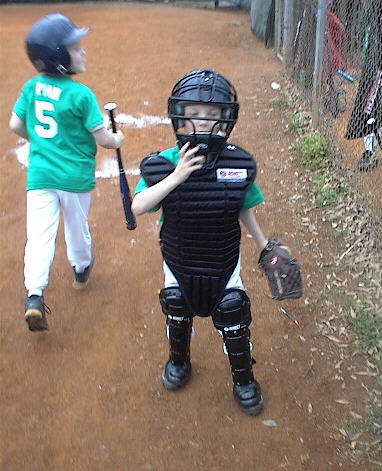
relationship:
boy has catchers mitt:
[130, 67, 291, 416] [257, 236, 303, 302]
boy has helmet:
[10, 12, 126, 331] [15, 10, 100, 70]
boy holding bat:
[10, 12, 126, 331] [102, 101, 136, 229]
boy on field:
[10, 12, 126, 331] [7, 0, 362, 457]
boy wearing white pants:
[5, 10, 137, 329] [22, 191, 96, 293]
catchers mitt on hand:
[257, 236, 303, 302] [173, 138, 206, 176]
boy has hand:
[127, 67, 295, 416] [173, 138, 206, 176]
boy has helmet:
[130, 67, 291, 416] [159, 71, 246, 182]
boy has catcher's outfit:
[130, 67, 291, 416] [146, 131, 266, 389]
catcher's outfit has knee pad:
[146, 131, 266, 389] [209, 288, 252, 330]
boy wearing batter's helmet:
[10, 12, 126, 331] [20, 10, 89, 77]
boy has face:
[127, 67, 295, 416] [183, 104, 223, 135]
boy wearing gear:
[127, 67, 295, 416] [138, 69, 255, 385]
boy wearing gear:
[130, 67, 291, 416] [138, 69, 255, 385]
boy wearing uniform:
[130, 67, 291, 416] [133, 141, 265, 292]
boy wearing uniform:
[10, 12, 126, 331] [7, 73, 114, 200]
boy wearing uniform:
[10, 12, 126, 331] [7, 71, 111, 334]